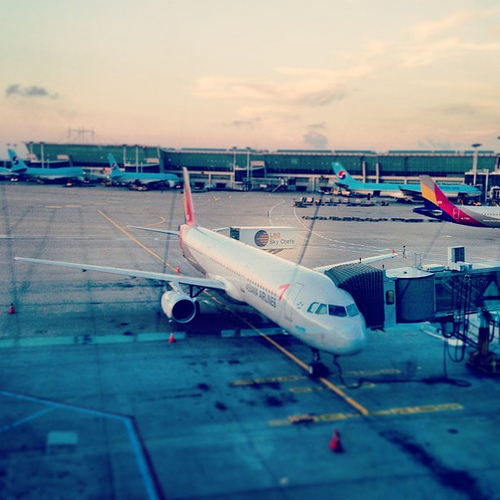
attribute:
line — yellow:
[96, 208, 179, 273]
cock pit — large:
[299, 294, 372, 334]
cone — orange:
[325, 426, 348, 457]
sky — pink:
[0, 2, 499, 152]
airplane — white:
[13, 153, 412, 385]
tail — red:
[161, 165, 208, 229]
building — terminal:
[13, 142, 499, 183]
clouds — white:
[197, 66, 351, 106]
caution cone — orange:
[327, 424, 347, 452]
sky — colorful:
[15, 11, 194, 56]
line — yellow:
[92, 207, 372, 422]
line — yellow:
[134, 209, 170, 229]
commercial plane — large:
[230, 250, 362, 365]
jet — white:
[19, 157, 431, 409]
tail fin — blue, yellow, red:
[421, 174, 456, 221]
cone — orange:
[329, 428, 343, 453]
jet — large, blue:
[322, 153, 496, 210]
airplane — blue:
[325, 156, 485, 213]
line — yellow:
[273, 400, 465, 427]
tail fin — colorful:
[414, 176, 466, 219]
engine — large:
[159, 272, 199, 326]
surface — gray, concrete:
[4, 181, 499, 499]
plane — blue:
[320, 161, 484, 206]